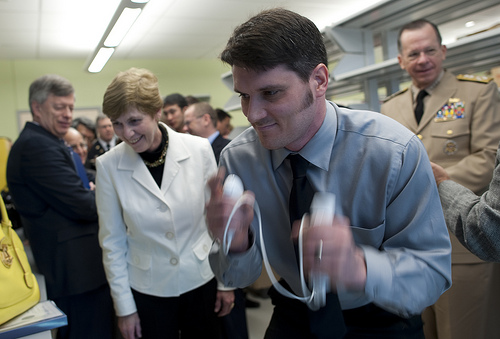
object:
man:
[206, 7, 459, 334]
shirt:
[208, 115, 440, 318]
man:
[371, 17, 499, 337]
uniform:
[372, 68, 500, 333]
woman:
[93, 65, 236, 328]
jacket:
[90, 136, 211, 310]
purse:
[4, 188, 40, 320]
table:
[4, 294, 69, 333]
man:
[3, 77, 122, 336]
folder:
[68, 145, 96, 192]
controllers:
[223, 172, 345, 309]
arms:
[288, 196, 402, 319]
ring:
[312, 243, 322, 262]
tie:
[285, 153, 315, 284]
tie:
[411, 87, 427, 122]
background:
[1, 1, 498, 322]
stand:
[0, 226, 73, 338]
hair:
[221, 7, 319, 61]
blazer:
[6, 127, 121, 299]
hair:
[30, 74, 70, 95]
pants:
[56, 282, 124, 338]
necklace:
[141, 134, 173, 173]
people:
[0, 3, 498, 339]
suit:
[2, 135, 101, 336]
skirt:
[128, 279, 216, 336]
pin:
[454, 110, 471, 123]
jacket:
[398, 73, 500, 146]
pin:
[456, 71, 494, 84]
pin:
[445, 95, 464, 104]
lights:
[74, 0, 147, 78]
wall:
[5, 3, 75, 57]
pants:
[128, 288, 218, 332]